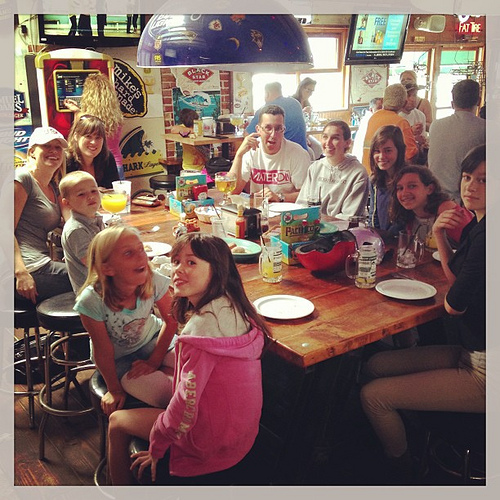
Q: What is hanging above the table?
A: A light.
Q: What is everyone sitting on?
A: Stools.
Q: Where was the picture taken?
A: A restaurant.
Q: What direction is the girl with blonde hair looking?
A: Right.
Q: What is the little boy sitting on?
A: A barstool.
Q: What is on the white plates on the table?
A: Nothing.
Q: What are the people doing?
A: Posing for a group photo.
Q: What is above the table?
A: A big light.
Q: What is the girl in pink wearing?
A: A hoodie.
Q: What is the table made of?
A: Wood.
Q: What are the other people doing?
A: Standing around.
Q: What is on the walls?
A: Advertisements.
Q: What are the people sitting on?
A: Bar stools.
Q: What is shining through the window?
A: The sun.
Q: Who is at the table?
A: A group of people.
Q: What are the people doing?
A: Sitting at a table.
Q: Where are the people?
A: At a restaurant.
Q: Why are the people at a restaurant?
A: They are hungry.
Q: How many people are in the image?
A: 19.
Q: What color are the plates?
A: White.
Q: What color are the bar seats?
A: Black.